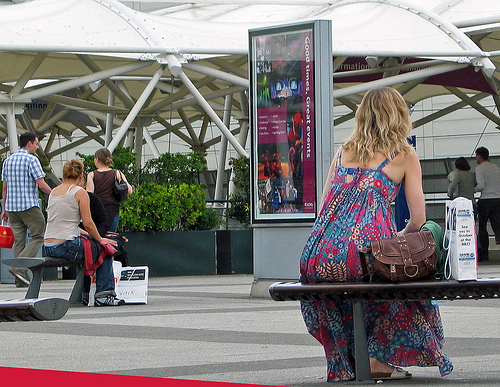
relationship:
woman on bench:
[309, 79, 445, 378] [271, 282, 499, 372]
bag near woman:
[445, 189, 476, 283] [309, 79, 445, 378]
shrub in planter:
[127, 188, 214, 226] [125, 237, 221, 273]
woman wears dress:
[309, 79, 445, 378] [303, 146, 453, 374]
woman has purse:
[309, 79, 445, 378] [365, 232, 438, 281]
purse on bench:
[365, 232, 438, 281] [271, 282, 499, 372]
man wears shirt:
[6, 132, 39, 290] [6, 157, 43, 211]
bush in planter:
[127, 188, 214, 226] [125, 237, 221, 273]